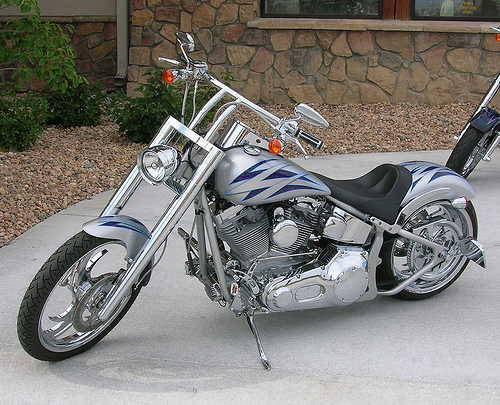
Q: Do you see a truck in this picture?
A: No, there are no trucks.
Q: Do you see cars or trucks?
A: No, there are no trucks or cars.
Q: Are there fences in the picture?
A: No, there are no fences.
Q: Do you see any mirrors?
A: Yes, there is a mirror.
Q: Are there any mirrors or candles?
A: Yes, there is a mirror.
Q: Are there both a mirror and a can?
A: No, there is a mirror but no cans.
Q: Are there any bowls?
A: No, there are no bowls.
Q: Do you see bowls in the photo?
A: No, there are no bowls.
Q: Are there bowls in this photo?
A: No, there are no bowls.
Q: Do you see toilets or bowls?
A: No, there are no bowls or toilets.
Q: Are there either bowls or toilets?
A: No, there are no bowls or toilets.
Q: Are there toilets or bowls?
A: No, there are no bowls or toilets.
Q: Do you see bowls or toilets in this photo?
A: No, there are no bowls or toilets.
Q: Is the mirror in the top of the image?
A: Yes, the mirror is in the top of the image.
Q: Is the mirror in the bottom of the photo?
A: No, the mirror is in the top of the image.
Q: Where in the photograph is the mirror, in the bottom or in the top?
A: The mirror is in the top of the image.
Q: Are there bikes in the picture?
A: Yes, there is a bike.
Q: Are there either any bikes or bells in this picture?
A: Yes, there is a bike.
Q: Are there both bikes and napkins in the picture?
A: No, there is a bike but no napkins.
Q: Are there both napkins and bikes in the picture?
A: No, there is a bike but no napkins.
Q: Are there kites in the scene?
A: No, there are no kites.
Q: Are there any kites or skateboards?
A: No, there are no kites or skateboards.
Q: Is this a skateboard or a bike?
A: This is a bike.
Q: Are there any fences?
A: No, there are no fences.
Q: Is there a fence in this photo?
A: No, there are no fences.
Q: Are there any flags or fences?
A: No, there are no fences or flags.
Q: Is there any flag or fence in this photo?
A: No, there are no fences or flags.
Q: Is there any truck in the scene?
A: No, there are no trucks.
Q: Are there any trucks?
A: No, there are no trucks.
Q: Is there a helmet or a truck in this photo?
A: No, there are no trucks or helmets.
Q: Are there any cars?
A: No, there are no cars.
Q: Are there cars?
A: No, there are no cars.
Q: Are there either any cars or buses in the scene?
A: No, there are no cars or buses.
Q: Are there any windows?
A: Yes, there is a window.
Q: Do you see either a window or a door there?
A: Yes, there is a window.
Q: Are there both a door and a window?
A: No, there is a window but no doors.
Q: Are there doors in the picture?
A: No, there are no doors.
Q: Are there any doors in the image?
A: No, there are no doors.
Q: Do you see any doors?
A: No, there are no doors.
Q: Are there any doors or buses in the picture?
A: No, there are no doors or buses.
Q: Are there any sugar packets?
A: No, there are no sugar packets.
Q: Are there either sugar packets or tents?
A: No, there are no sugar packets or tents.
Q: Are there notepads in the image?
A: No, there are no notepads.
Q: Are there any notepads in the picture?
A: No, there are no notepads.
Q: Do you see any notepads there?
A: No, there are no notepads.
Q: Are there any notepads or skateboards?
A: No, there are no notepads or skateboards.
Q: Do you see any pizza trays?
A: No, there are no pizza trays.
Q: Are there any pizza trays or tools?
A: No, there are no pizza trays or tools.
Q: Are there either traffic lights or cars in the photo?
A: No, there are no cars or traffic lights.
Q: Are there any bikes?
A: Yes, there is a bike.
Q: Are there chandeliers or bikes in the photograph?
A: Yes, there is a bike.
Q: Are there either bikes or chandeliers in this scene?
A: Yes, there is a bike.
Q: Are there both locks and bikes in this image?
A: No, there is a bike but no locks.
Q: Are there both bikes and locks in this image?
A: No, there is a bike but no locks.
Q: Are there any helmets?
A: No, there are no helmets.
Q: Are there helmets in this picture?
A: No, there are no helmets.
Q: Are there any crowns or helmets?
A: No, there are no helmets or crowns.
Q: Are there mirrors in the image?
A: Yes, there is a mirror.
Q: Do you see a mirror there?
A: Yes, there is a mirror.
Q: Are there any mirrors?
A: Yes, there is a mirror.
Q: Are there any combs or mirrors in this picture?
A: Yes, there is a mirror.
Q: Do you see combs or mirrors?
A: Yes, there is a mirror.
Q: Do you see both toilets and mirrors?
A: No, there is a mirror but no toilets.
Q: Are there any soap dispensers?
A: No, there are no soap dispensers.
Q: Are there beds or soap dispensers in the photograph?
A: No, there are no soap dispensers or beds.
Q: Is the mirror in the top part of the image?
A: Yes, the mirror is in the top of the image.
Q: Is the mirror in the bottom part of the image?
A: No, the mirror is in the top of the image.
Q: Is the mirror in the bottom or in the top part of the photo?
A: The mirror is in the top of the image.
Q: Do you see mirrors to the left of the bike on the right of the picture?
A: Yes, there is a mirror to the left of the bike.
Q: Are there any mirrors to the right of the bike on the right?
A: No, the mirror is to the left of the bike.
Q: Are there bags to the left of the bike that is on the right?
A: No, there is a mirror to the left of the bike.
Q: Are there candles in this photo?
A: No, there are no candles.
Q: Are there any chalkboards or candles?
A: No, there are no candles or chalkboards.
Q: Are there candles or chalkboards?
A: No, there are no candles or chalkboards.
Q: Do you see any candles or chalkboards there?
A: No, there are no candles or chalkboards.